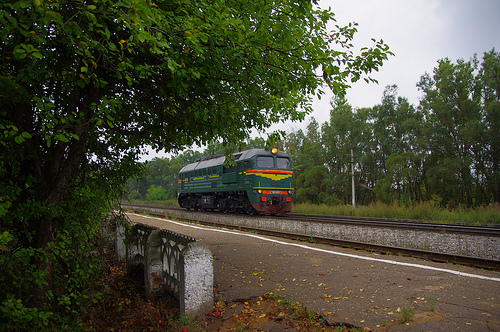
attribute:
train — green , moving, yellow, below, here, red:
[183, 143, 306, 216]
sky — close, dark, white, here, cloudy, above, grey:
[369, 7, 475, 51]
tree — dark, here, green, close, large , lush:
[375, 90, 464, 165]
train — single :
[176, 141, 296, 223]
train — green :
[166, 143, 297, 224]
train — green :
[170, 145, 302, 219]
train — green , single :
[167, 141, 300, 214]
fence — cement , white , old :
[93, 205, 217, 326]